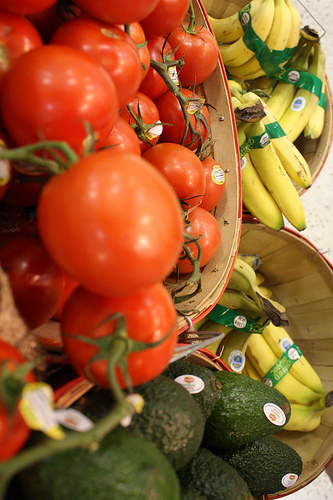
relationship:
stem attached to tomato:
[3, 130, 90, 168] [28, 153, 186, 294]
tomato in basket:
[155, 87, 211, 149] [175, 0, 242, 335]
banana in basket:
[246, 111, 308, 232] [225, 5, 328, 178]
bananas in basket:
[190, 252, 331, 431] [242, 240, 333, 485]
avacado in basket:
[15, 434, 179, 498] [293, 431, 330, 485]